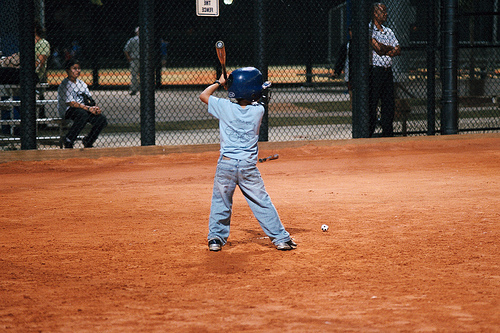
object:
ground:
[0, 160, 495, 329]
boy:
[198, 66, 299, 252]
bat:
[214, 39, 231, 92]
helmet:
[226, 66, 273, 105]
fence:
[0, 0, 499, 152]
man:
[368, 2, 402, 138]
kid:
[57, 58, 109, 149]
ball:
[320, 223, 332, 231]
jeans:
[62, 107, 108, 149]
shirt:
[207, 95, 266, 163]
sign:
[195, 0, 219, 16]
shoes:
[273, 237, 299, 250]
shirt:
[369, 20, 401, 67]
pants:
[206, 155, 294, 245]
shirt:
[58, 77, 97, 120]